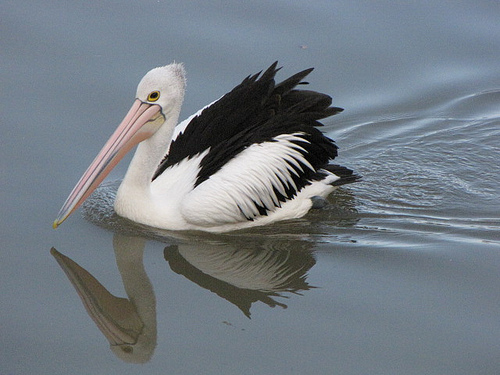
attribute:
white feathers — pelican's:
[179, 179, 286, 225]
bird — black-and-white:
[30, 54, 401, 265]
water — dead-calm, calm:
[5, 2, 497, 373]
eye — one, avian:
[148, 87, 160, 101]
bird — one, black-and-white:
[36, 56, 360, 239]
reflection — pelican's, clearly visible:
[47, 226, 324, 367]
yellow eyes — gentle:
[143, 85, 163, 105]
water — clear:
[43, 243, 352, 356]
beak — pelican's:
[20, 105, 160, 270]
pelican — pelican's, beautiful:
[53, 63, 354, 235]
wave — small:
[386, 114, 491, 227]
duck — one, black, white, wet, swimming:
[52, 60, 357, 232]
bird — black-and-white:
[39, 60, 372, 264]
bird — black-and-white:
[1, 2, 495, 374]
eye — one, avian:
[146, 89, 166, 100]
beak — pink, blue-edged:
[52, 97, 164, 227]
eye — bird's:
[146, 90, 160, 101]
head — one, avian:
[51, 55, 187, 257]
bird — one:
[42, 44, 343, 264]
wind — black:
[185, 125, 341, 228]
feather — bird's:
[255, 52, 326, 121]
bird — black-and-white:
[43, 51, 380, 258]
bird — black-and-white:
[53, 56, 363, 230]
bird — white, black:
[47, 37, 361, 268]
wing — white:
[188, 117, 339, 230]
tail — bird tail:
[232, 60, 382, 182]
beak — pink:
[53, 104, 157, 244]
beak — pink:
[47, 99, 170, 230]